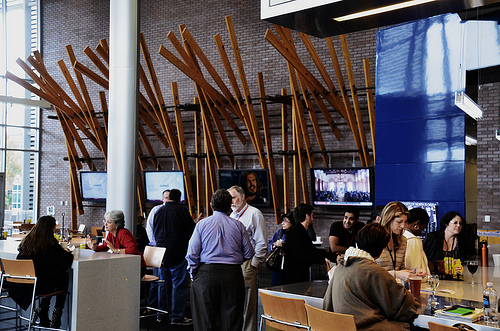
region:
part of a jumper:
[340, 276, 397, 306]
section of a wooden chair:
[273, 296, 298, 316]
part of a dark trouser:
[198, 266, 242, 305]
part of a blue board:
[397, 107, 456, 156]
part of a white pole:
[105, 137, 137, 205]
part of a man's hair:
[211, 188, 230, 211]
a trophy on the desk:
[425, 271, 437, 301]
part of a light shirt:
[250, 209, 267, 231]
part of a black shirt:
[161, 198, 186, 248]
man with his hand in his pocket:
[185, 189, 255, 324]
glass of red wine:
[462, 254, 482, 286]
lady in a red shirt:
[85, 211, 139, 256]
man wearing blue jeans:
[152, 190, 189, 330]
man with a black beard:
[283, 201, 325, 275]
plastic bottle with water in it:
[480, 280, 497, 323]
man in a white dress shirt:
[229, 184, 264, 329]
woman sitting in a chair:
[23, 210, 74, 330]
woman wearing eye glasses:
[442, 207, 464, 242]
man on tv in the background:
[240, 170, 269, 194]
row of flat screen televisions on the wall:
[80, 169, 373, 210]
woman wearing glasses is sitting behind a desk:
[86, 209, 148, 314]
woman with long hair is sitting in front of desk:
[16, 214, 68, 320]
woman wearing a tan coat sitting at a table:
[320, 225, 425, 327]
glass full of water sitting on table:
[429, 274, 440, 299]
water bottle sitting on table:
[482, 281, 496, 322]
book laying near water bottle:
[435, 303, 482, 323]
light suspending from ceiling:
[452, 0, 492, 120]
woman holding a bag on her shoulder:
[268, 211, 298, 282]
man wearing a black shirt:
[327, 209, 369, 268]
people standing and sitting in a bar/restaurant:
[24, 165, 491, 317]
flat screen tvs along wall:
[55, 156, 406, 216]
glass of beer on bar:
[402, 265, 425, 307]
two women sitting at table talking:
[15, 194, 132, 309]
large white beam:
[90, 0, 156, 250]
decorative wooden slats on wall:
[179, 11, 348, 184]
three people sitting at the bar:
[346, 205, 478, 324]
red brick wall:
[70, 23, 274, 109]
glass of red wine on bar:
[458, 256, 482, 289]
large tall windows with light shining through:
[5, 3, 51, 228]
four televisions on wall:
[65, 165, 395, 215]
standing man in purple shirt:
[182, 183, 257, 288]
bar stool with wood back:
[250, 283, 312, 329]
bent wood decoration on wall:
[182, 43, 364, 157]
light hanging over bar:
[448, 76, 487, 128]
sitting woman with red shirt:
[82, 209, 149, 274]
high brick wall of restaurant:
[48, 26, 92, 185]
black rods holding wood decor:
[226, 88, 346, 128]